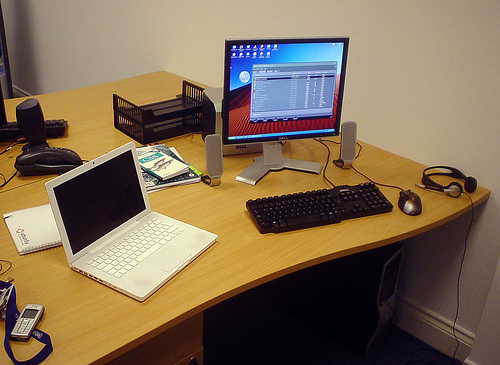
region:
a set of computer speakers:
[186, 122, 366, 197]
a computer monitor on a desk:
[211, 19, 363, 202]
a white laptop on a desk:
[51, 142, 199, 312]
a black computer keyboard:
[234, 177, 386, 237]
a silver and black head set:
[416, 148, 485, 208]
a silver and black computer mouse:
[394, 177, 428, 219]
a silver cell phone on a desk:
[3, 293, 49, 351]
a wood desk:
[3, 169, 478, 348]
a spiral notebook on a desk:
[6, 197, 56, 255]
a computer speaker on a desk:
[193, 127, 229, 192]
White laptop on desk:
[40, 138, 227, 300]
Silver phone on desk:
[10, 298, 47, 348]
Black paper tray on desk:
[103, 78, 213, 146]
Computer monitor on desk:
[218, 26, 345, 176]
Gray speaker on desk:
[332, 115, 368, 174]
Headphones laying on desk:
[411, 143, 482, 202]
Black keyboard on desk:
[235, 174, 397, 237]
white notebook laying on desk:
[3, 195, 70, 256]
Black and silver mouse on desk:
[383, 177, 428, 227]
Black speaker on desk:
[9, 95, 54, 154]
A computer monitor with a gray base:
[217, 35, 349, 183]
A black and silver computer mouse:
[395, 188, 424, 217]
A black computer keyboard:
[239, 181, 395, 236]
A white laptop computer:
[43, 140, 218, 302]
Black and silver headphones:
[417, 163, 481, 200]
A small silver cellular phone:
[11, 300, 45, 345]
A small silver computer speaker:
[330, 118, 360, 173]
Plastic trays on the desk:
[105, 78, 217, 146]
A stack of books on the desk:
[118, 140, 205, 204]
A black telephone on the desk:
[14, 140, 84, 175]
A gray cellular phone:
[21, 301, 43, 345]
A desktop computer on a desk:
[228, 36, 392, 228]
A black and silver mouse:
[393, 183, 428, 228]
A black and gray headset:
[418, 153, 484, 205]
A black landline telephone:
[23, 146, 79, 177]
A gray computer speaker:
[328, 127, 376, 169]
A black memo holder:
[110, 90, 217, 131]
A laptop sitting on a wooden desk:
[33, 173, 221, 282]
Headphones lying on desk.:
[420, 155, 478, 203]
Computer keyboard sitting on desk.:
[242, 183, 396, 238]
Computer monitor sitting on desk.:
[220, 23, 351, 185]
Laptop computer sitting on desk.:
[41, 136, 222, 306]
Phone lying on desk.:
[10, 300, 50, 342]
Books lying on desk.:
[137, 140, 205, 193]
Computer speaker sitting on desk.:
[201, 132, 231, 192]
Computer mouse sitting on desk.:
[396, 180, 429, 220]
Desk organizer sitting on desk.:
[111, 79, 208, 147]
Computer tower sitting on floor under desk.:
[364, 243, 411, 348]